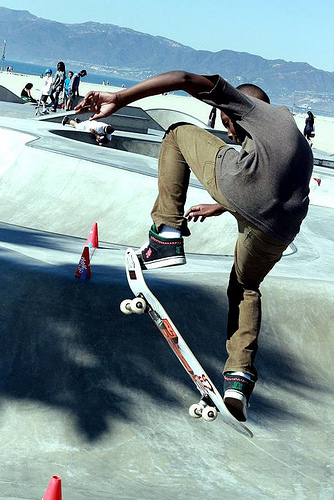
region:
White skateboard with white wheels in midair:
[119, 247, 253, 442]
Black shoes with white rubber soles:
[135, 225, 255, 423]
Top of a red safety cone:
[41, 473, 62, 498]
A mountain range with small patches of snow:
[0, 5, 333, 97]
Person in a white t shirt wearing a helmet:
[38, 66, 54, 116]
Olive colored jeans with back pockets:
[150, 119, 289, 379]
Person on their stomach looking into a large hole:
[56, 113, 114, 144]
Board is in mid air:
[113, 247, 261, 445]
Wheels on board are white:
[110, 296, 219, 422]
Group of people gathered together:
[22, 60, 86, 128]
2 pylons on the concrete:
[62, 211, 107, 293]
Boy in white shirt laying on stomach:
[64, 109, 117, 145]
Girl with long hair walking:
[300, 108, 319, 154]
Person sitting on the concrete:
[13, 78, 40, 108]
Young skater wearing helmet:
[35, 62, 55, 110]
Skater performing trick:
[69, 60, 319, 442]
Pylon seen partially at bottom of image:
[39, 467, 74, 498]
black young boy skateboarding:
[77, 65, 308, 418]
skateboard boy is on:
[105, 239, 253, 434]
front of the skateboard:
[218, 392, 256, 439]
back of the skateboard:
[123, 244, 144, 285]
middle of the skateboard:
[146, 302, 203, 376]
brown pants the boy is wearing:
[149, 121, 292, 377]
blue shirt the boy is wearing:
[216, 91, 310, 252]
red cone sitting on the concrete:
[41, 474, 62, 498]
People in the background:
[19, 59, 83, 114]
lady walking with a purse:
[303, 109, 315, 147]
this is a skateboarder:
[178, 69, 333, 356]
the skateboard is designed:
[112, 272, 234, 451]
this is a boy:
[125, 123, 257, 331]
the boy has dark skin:
[125, 58, 279, 317]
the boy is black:
[112, 70, 318, 298]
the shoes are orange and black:
[117, 219, 164, 285]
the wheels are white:
[109, 297, 149, 322]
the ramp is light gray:
[51, 322, 144, 426]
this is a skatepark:
[18, 154, 211, 422]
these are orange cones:
[62, 233, 115, 296]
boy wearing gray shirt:
[181, 64, 317, 318]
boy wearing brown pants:
[202, 64, 317, 316]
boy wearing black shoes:
[201, 69, 319, 392]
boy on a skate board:
[119, 59, 305, 439]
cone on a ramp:
[70, 239, 96, 278]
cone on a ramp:
[38, 469, 67, 492]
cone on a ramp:
[81, 214, 103, 245]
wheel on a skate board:
[188, 394, 218, 425]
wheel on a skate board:
[115, 294, 147, 318]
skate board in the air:
[121, 245, 144, 394]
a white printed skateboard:
[120, 245, 253, 438]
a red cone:
[40, 474, 61, 498]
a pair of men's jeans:
[147, 118, 293, 372]